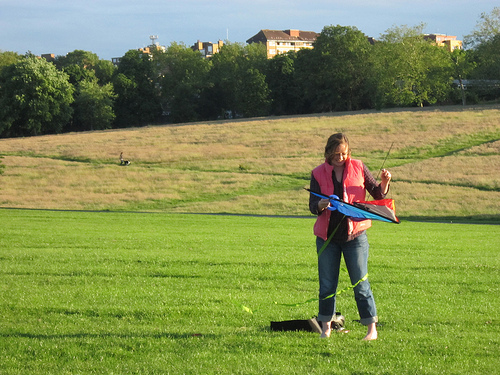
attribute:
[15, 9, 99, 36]
cloud — white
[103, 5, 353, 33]
cloud — white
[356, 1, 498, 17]
cloud — white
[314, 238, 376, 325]
jeans — blue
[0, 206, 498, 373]
green grass — brown, short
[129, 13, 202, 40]
clouds — white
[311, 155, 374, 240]
vest — red, puffy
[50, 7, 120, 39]
clouds — white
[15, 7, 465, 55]
sky — blue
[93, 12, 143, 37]
clouds — white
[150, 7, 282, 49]
sky — blue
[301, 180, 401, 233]
kite — blue, red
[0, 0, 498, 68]
sky — blue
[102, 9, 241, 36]
clouds — white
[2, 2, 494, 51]
sky — blue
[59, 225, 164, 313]
grass — green, brown, short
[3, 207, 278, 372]
grass — brown, short, green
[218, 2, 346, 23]
clouds — white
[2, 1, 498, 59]
clouds — white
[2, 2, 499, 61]
sky — blue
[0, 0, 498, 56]
sky — blue